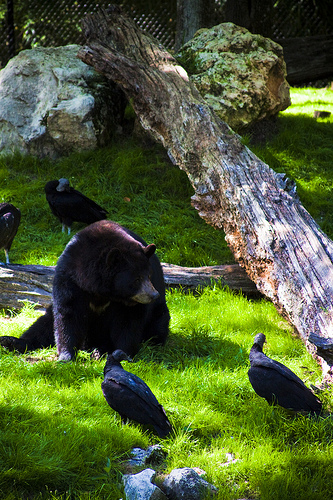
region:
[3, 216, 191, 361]
black bear sitting in shady grass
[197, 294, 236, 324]
bright green grass in a sun-dappled patch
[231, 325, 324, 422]
large black bird on the ground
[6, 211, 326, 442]
bear is focused on bird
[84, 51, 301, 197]
large fallen log resting on boulder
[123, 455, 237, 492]
moss covered rocks in the grass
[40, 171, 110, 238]
large vulture standing behind a bear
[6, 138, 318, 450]
bear and birds resting on the ground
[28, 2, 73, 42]
fencing to the zoo enclosure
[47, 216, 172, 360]
brown bear sitting in the grass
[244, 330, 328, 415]
black bird perched in the grass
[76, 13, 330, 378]
large log laying across the grass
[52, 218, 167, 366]
a large brown bear is looking at a bird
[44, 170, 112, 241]
black bird in the background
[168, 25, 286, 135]
large rock in the bear exhibit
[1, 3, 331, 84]
fence in the back of the bear habitat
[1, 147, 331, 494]
bright green grass on the ground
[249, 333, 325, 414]
this bird is looking to the right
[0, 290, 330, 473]
area in the grass where the sun is shining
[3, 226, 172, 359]
bear on the ground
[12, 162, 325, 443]
lawn with thick green grass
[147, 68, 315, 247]
log from a tree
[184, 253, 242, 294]
log from a tree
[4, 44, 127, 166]
rock behind the bear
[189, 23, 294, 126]
rock behind the bear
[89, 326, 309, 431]
birds in front of bear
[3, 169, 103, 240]
birds behind the bear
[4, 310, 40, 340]
grass on wood structure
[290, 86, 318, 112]
sunlight on the grass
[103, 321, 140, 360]
A bear and two birds standing in the grass.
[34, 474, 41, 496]
A bear and two birds standing in the grass.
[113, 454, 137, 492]
A bear and two birds standing in the grass.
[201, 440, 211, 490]
A bear and two birds standing in the grass.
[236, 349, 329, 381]
A bear and two birds standing in the grass.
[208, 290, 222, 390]
A bear and two birds standing in the grass.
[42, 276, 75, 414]
A bear and two birds standing in the grass.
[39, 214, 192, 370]
large bear with dark hair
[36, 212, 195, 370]
large bear sitting with several birds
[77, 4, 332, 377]
a very large log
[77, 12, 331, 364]
a dead tree laying on the ground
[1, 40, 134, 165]
large boulder supporting a dead tree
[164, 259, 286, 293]
log laying on the ground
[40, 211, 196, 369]
bear looking at a bird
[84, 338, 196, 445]
bird not concerned about the bear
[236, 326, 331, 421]
a bird looking at something out of picture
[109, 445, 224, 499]
some rocks